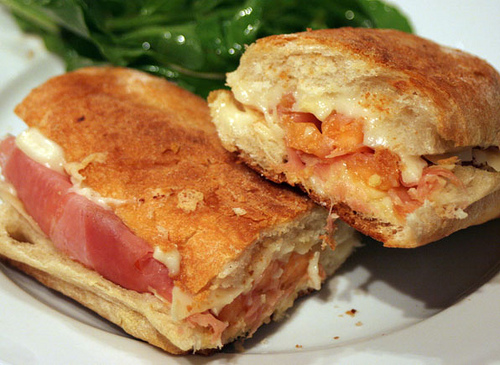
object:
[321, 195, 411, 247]
crispy edge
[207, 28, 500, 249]
bread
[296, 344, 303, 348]
crumbs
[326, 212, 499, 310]
shadow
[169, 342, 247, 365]
shadow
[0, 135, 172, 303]
ham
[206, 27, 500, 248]
sandwich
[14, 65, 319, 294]
crust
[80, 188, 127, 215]
melted cheese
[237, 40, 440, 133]
dough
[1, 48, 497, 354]
white plate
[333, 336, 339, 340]
crumbs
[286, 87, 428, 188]
cheese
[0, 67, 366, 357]
sandwich roll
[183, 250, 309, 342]
red meat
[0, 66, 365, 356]
bread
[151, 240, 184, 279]
cheese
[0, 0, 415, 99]
leaves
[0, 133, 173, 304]
meat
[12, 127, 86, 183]
cheese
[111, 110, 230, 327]
food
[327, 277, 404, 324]
border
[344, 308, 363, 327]
bread crumbs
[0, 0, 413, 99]
green vegetable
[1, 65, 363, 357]
sandwich